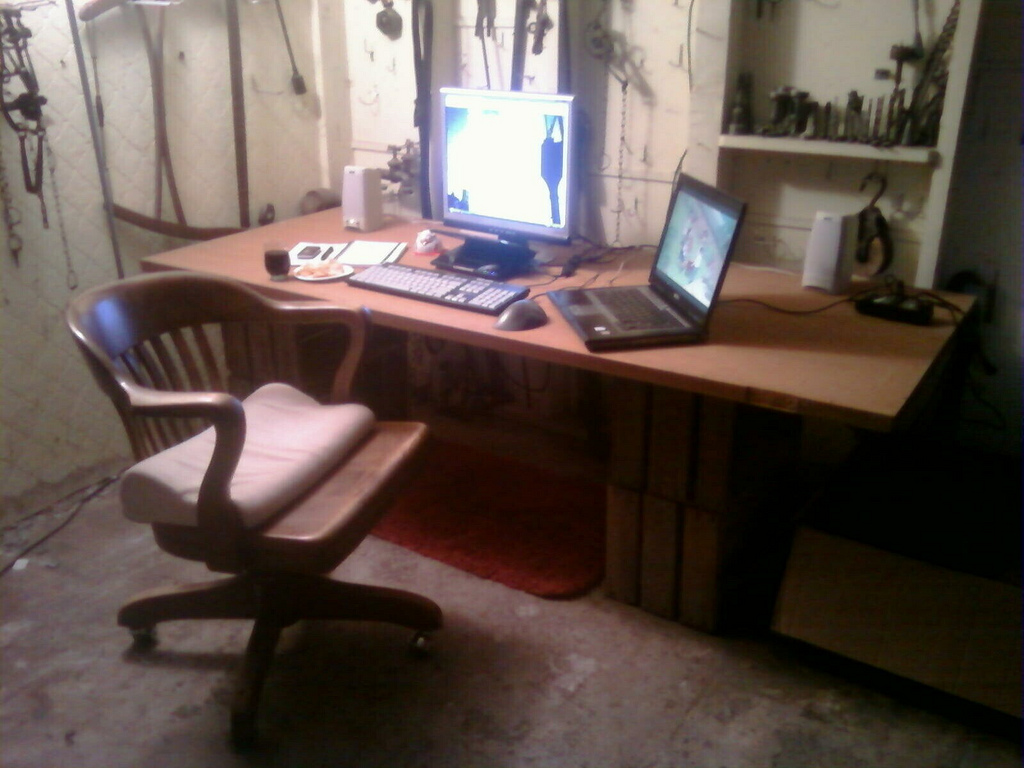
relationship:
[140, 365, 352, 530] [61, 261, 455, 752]
seat on chair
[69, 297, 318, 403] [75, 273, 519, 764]
back of chair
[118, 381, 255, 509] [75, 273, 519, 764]
right arm of chair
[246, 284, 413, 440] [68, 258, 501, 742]
left arm of chair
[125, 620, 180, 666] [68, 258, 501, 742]
wheel of chair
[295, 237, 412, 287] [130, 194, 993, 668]
paper on desk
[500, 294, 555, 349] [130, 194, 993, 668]
mouse on desk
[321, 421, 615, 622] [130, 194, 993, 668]
rug under desk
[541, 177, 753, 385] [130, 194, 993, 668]
laptop on top of desk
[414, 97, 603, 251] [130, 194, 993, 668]
monitor on top of desk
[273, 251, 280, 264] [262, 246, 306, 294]
drink in glass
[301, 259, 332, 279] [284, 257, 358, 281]
food on plate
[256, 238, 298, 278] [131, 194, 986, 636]
glass sitting on desk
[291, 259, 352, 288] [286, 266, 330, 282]
plate full of food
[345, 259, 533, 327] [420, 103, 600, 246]
keyboard in front of monitor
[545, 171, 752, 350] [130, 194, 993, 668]
laptop on a desk